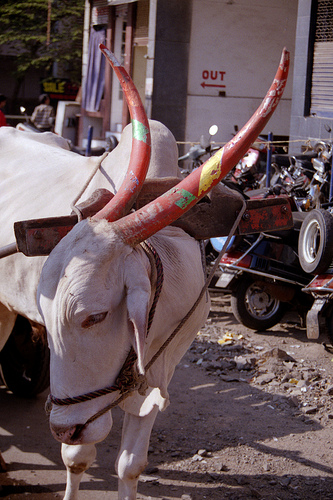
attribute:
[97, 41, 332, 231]
horns — painted, red, long, decorated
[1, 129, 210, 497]
goat — white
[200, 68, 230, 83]
out — written, red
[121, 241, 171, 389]
rope — brown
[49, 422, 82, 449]
nose — pink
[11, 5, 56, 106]
tree — large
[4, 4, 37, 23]
leaves — green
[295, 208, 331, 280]
tire — black, rubber, used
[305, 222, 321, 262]
rim — metal, white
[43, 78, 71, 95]
sign — yellow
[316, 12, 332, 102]
curtain — purple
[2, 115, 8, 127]
shirt — red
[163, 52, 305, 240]
horn — painted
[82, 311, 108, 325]
eye — large, slanted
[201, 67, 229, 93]
sign — red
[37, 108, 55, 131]
shirt — brown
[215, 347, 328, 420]
dirt — littered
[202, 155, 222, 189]
paint — yellow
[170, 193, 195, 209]
paint — green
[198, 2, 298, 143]
building — white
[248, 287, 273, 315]
rim — metal